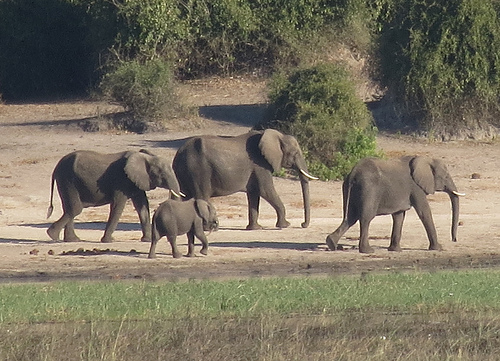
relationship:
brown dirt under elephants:
[3, 79, 498, 269] [326, 155, 464, 260]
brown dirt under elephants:
[3, 79, 498, 269] [171, 127, 314, 229]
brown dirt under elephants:
[3, 79, 498, 269] [144, 197, 218, 257]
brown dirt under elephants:
[3, 79, 498, 269] [43, 149, 185, 245]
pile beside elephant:
[24, 246, 145, 259] [42, 150, 184, 245]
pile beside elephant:
[24, 246, 145, 259] [146, 195, 218, 260]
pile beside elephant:
[24, 246, 145, 259] [174, 127, 309, 225]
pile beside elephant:
[24, 246, 145, 259] [323, 146, 460, 256]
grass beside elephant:
[4, 265, 499, 357] [331, 151, 461, 254]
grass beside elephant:
[4, 265, 499, 357] [174, 127, 309, 225]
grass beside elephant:
[4, 265, 499, 357] [147, 200, 219, 256]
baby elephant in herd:
[157, 192, 221, 252] [46, 120, 466, 252]